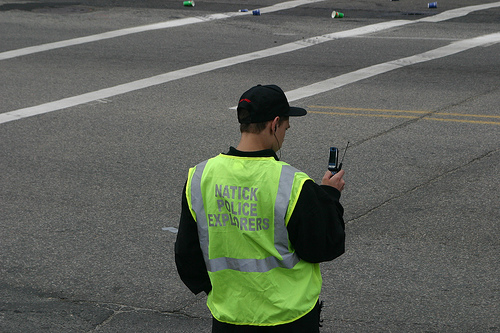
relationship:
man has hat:
[156, 74, 345, 330] [220, 81, 299, 118]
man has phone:
[156, 74, 345, 330] [314, 139, 347, 171]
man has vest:
[156, 74, 345, 330] [177, 160, 305, 315]